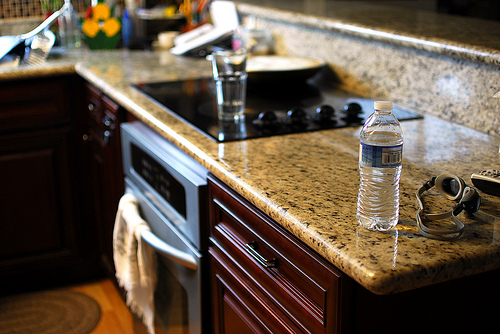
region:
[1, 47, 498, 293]
Marble kitchen counter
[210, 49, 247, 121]
Glass on the kitchen counter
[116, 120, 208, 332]
Oven in the kitchen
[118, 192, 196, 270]
Handle on the oven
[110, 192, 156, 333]
Towel hanging on the oven handle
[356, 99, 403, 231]
Water bottle on the counter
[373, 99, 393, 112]
Cap of the water bottle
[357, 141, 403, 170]
Label on the water bottle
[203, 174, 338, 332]
Drawer on the cabinet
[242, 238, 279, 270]
Handle on the drawer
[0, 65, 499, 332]
kitchen cabinet are cherry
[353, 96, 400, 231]
water bottle on top of counter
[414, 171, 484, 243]
swimming goggles next to water bottle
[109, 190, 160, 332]
towel hanging from oven handle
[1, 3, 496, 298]
granite counter top in kitchen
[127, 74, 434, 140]
black stove top on counter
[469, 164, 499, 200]
remote control next to goggles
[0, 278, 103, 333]
rug on kitchen floor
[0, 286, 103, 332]
kitchen rug is brown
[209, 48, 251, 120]
clear glass on top of stove top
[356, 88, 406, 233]
Water bottle on counter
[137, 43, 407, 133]
Electric stove top is black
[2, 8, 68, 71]
Pan in kitchen sink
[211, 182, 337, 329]
Dark brown wooden kitchen cabinet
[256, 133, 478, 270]
Tan colored marble countertop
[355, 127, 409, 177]
Blue label on water bottle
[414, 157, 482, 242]
Goggles on marble countertop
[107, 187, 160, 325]
Kitchen towel on oven handle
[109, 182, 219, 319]
Door to the oven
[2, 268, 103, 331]
Placemat on kitchen floor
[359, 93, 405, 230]
a plastic water bottle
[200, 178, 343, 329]
a brown cabinet drawer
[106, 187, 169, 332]
a white towel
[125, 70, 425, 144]
a black stove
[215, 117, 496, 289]
part of a kitchen counter top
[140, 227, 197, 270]
part of an oven handle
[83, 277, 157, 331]
a section of hardwood floor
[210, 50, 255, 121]
a tall glass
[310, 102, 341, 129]
a black stove knob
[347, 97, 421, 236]
clear plastic bottle of water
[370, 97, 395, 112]
white cap on the bottle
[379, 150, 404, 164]
black and white barcode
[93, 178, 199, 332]
white towel hanging on the stove door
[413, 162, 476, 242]
goggles on the counter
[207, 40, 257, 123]
clear glass on the stovetop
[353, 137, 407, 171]
blue label wrapped around the bottle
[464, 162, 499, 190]
half of a remote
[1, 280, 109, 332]
small rug on the floor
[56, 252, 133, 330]
light brown wood on the floor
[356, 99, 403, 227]
a clear plastic water bottle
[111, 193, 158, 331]
a white towel hanging on the oven door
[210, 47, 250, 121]
a clear glass of water